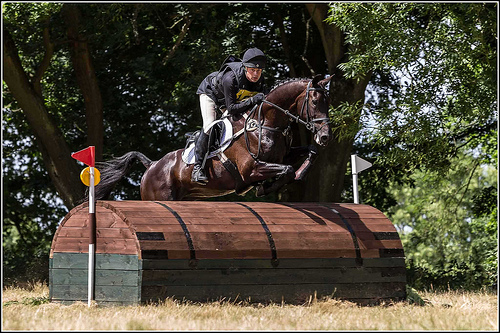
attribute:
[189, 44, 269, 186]
jockey — jumping, riding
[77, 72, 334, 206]
horse — mid-air, jumping, shinign, jupming, dark brown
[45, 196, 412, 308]
obstacle — brown, black, wooden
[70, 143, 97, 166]
flag — red, small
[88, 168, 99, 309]
post — white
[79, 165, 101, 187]
circle — small, yellow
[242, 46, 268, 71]
hat — black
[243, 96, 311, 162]
bridle — black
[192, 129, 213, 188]
boots — black, knee-high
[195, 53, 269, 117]
shirt — black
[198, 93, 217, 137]
pants — white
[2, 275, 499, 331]
grass — dry, yellow, brown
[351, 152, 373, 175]
flag — white, small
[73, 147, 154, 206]
tail — long, hair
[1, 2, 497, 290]
leaves — green